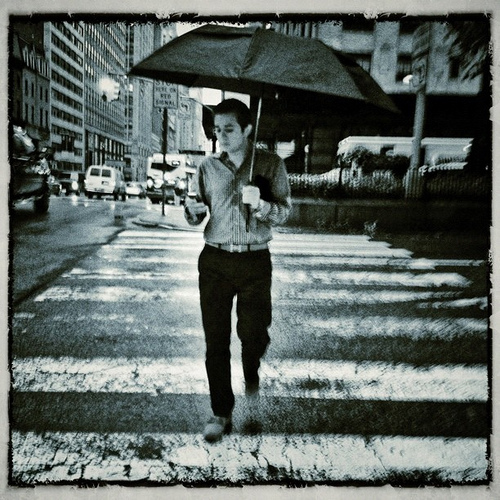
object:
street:
[6, 137, 500, 496]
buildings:
[87, 24, 132, 184]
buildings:
[43, 19, 83, 180]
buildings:
[130, 20, 152, 180]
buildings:
[150, 22, 175, 183]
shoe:
[202, 411, 232, 442]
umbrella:
[123, 23, 399, 234]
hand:
[185, 198, 208, 216]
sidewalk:
[137, 195, 207, 235]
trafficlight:
[98, 77, 117, 98]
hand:
[242, 183, 260, 208]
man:
[183, 99, 292, 440]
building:
[11, 19, 53, 190]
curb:
[132, 215, 161, 226]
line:
[9, 434, 489, 481]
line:
[11, 354, 487, 404]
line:
[311, 314, 487, 339]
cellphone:
[187, 192, 206, 218]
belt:
[201, 240, 273, 254]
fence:
[292, 165, 321, 200]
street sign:
[159, 107, 175, 216]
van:
[80, 165, 127, 202]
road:
[12, 188, 498, 498]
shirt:
[180, 149, 292, 246]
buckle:
[230, 244, 242, 252]